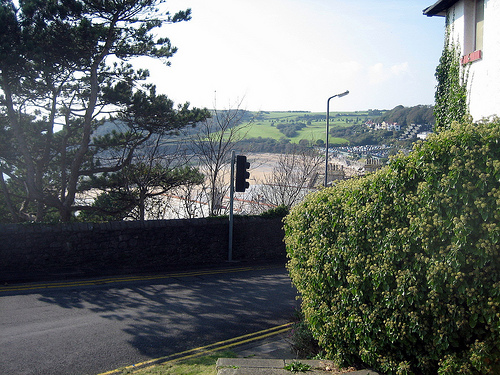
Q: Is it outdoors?
A: Yes, it is outdoors.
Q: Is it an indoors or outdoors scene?
A: It is outdoors.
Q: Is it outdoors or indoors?
A: It is outdoors.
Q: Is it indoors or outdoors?
A: It is outdoors.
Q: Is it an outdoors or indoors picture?
A: It is outdoors.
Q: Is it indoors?
A: No, it is outdoors.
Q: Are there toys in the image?
A: No, there are no toys.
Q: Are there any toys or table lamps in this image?
A: No, there are no toys or table lamps.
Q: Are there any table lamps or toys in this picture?
A: No, there are no toys or table lamps.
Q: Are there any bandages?
A: No, there are no bandages.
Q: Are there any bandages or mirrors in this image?
A: No, there are no bandages or mirrors.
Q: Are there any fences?
A: No, there are no fences.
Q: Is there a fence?
A: No, there are no fences.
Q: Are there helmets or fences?
A: No, there are no fences or helmets.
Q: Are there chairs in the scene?
A: No, there are no chairs.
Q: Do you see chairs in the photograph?
A: No, there are no chairs.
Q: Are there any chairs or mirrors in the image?
A: No, there are no chairs or mirrors.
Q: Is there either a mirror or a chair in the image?
A: No, there are no chairs or mirrors.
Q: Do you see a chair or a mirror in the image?
A: No, there are no chairs or mirrors.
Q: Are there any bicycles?
A: No, there are no bicycles.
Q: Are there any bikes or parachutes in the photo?
A: No, there are no bikes or parachutes.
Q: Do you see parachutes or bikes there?
A: No, there are no bikes or parachutes.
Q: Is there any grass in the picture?
A: Yes, there is grass.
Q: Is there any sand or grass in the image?
A: Yes, there is grass.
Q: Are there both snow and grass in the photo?
A: No, there is grass but no snow.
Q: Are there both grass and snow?
A: No, there is grass but no snow.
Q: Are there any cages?
A: No, there are no cages.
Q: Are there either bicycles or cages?
A: No, there are no cages or bicycles.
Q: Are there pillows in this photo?
A: No, there are no pillows.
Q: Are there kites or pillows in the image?
A: No, there are no pillows or kites.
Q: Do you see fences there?
A: No, there are no fences.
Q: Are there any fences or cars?
A: No, there are no fences or cars.